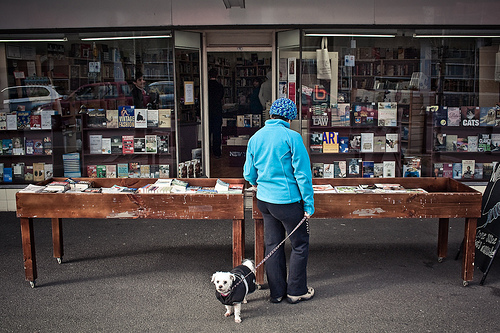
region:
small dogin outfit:
[213, 251, 264, 313]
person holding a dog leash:
[111, 191, 319, 322]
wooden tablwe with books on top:
[31, 165, 233, 330]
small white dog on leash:
[189, 255, 264, 330]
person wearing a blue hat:
[255, 92, 312, 124]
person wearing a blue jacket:
[241, 114, 316, 227]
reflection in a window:
[13, 65, 159, 135]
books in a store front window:
[14, 92, 164, 155]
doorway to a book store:
[126, 56, 285, 239]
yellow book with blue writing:
[302, 124, 341, 174]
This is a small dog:
[175, 246, 290, 329]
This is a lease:
[224, 262, 251, 277]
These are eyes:
[206, 277, 231, 284]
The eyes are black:
[206, 279, 232, 289]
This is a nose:
[215, 283, 221, 291]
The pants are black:
[270, 172, 305, 276]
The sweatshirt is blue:
[227, 155, 316, 200]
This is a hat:
[275, 95, 292, 123]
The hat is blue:
[265, 100, 283, 121]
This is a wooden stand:
[164, 163, 172, 273]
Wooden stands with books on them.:
[17, 167, 484, 290]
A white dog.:
[208, 258, 263, 322]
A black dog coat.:
[210, 263, 257, 305]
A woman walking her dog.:
[211, 97, 331, 323]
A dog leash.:
[222, 214, 312, 291]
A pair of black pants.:
[256, 197, 307, 298]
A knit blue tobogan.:
[269, 97, 298, 119]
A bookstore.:
[3, 38, 498, 215]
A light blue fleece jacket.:
[241, 118, 313, 216]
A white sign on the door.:
[182, 80, 197, 102]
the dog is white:
[196, 260, 267, 330]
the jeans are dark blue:
[255, 205, 312, 293]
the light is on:
[75, 25, 174, 57]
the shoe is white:
[286, 284, 323, 306]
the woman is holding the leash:
[294, 210, 316, 240]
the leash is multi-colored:
[252, 231, 295, 260]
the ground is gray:
[338, 233, 403, 318]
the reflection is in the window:
[22, 52, 170, 107]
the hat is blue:
[266, 92, 300, 122]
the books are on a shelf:
[302, 92, 407, 132]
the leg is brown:
[20, 224, 38, 272]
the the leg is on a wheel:
[25, 276, 35, 288]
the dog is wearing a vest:
[186, 247, 269, 324]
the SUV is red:
[47, 75, 136, 115]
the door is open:
[204, 27, 276, 128]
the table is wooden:
[3, 175, 246, 250]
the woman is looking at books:
[239, 90, 334, 305]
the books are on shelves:
[438, 106, 494, 179]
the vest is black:
[206, 259, 258, 311]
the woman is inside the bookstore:
[121, 66, 162, 106]